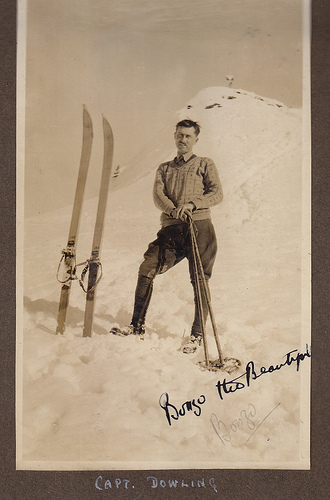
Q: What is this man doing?
A: Skiing.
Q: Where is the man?
A: A mountain.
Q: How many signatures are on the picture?
A: One.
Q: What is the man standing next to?
A: A pair of skis.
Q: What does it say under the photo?
A: Capt. Dowling.